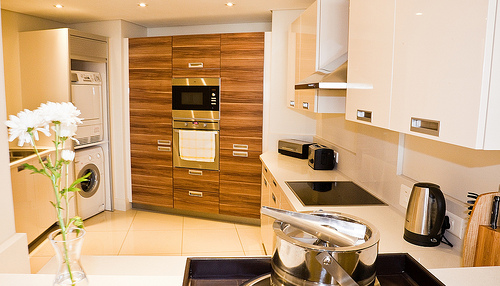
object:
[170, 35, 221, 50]
area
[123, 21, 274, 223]
wall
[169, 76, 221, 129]
oven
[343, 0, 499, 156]
cupboard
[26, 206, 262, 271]
floor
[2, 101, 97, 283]
flowers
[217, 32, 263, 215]
door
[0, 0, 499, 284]
modern kitchen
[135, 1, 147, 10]
lights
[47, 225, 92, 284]
vessel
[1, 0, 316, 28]
ceiling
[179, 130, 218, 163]
towel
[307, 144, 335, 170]
toaster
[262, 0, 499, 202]
ground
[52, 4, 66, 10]
light bulb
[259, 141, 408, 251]
table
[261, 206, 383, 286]
pot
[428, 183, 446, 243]
handle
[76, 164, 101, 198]
round window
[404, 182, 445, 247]
kettle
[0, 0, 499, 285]
room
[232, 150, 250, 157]
handle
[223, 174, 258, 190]
area